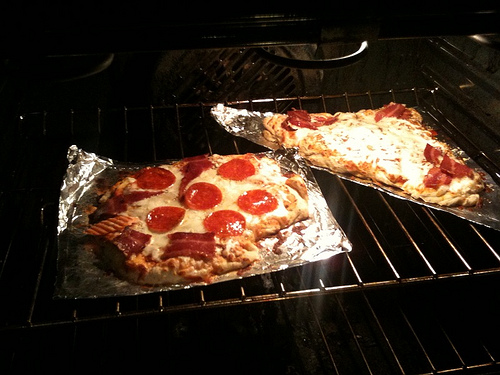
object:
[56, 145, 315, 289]
pizza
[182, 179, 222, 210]
pepperoni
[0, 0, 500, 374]
oven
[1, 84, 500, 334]
rack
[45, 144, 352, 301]
tinfoil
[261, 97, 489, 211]
pizza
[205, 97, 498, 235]
tinfoil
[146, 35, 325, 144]
fan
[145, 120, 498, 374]
lower rack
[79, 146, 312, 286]
crust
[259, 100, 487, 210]
crust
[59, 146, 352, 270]
reflected light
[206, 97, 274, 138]
reflected light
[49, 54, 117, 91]
hose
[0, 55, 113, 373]
right wall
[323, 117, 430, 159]
ramen [?]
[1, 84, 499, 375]
oven racks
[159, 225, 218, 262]
bacon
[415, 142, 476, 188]
bacon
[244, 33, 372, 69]
light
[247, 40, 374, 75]
heating coil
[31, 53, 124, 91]
heating coil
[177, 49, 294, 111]
air vents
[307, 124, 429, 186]
no central meat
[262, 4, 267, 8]
freezer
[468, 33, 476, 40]
light source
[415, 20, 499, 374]
left wall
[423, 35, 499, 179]
grooves for racks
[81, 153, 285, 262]
toppings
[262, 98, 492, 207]
toppings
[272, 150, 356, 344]
rays of light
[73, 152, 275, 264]
pepperoni & bacon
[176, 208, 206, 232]
grease